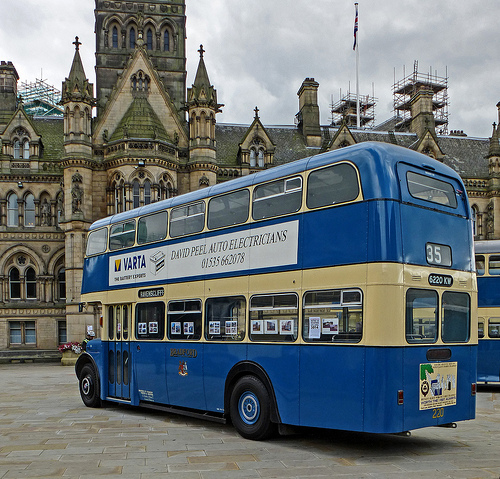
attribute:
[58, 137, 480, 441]
bus — double decker , blue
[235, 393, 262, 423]
rim — blue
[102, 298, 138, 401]
door — folding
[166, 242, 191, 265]
david — black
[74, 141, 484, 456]
bus — double decker, parked, blue, tan, yellow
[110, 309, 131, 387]
door — yellow and blue 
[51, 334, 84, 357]
flowers — building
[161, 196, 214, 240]
windows — building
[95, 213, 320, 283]
logo — bus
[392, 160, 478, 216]
window — rectangular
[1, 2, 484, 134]
sky — blue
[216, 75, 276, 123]
cloud — white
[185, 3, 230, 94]
cloud — white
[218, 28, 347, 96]
cloud — white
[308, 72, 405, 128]
cloud — white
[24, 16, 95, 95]
cloud — white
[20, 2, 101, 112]
cloud — white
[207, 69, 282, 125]
cloud — white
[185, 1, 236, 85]
cloud — white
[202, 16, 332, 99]
cloud — white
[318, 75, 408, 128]
cloud — white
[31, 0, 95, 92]
cloud — white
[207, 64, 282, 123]
cloud — white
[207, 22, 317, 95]
cloud — white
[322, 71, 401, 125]
cloud — white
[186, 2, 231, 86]
cloud — white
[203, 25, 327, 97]
cloud — white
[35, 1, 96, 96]
cloud — white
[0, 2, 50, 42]
cloud — white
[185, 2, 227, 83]
cloud — white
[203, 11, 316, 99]
cloud — white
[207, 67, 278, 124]
cloud — white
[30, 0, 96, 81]
cloud — white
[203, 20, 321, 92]
cloud — white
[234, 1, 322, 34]
cloud — white